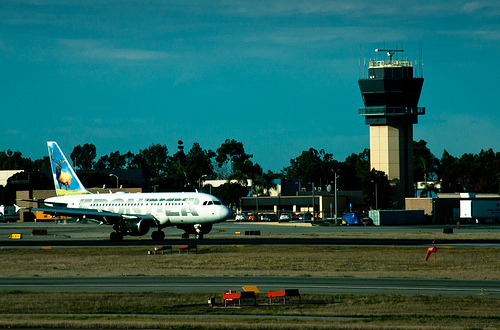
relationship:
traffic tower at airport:
[346, 28, 428, 232] [13, 77, 496, 247]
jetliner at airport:
[45, 145, 248, 256] [26, 79, 496, 286]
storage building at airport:
[360, 190, 450, 231] [159, 63, 497, 272]